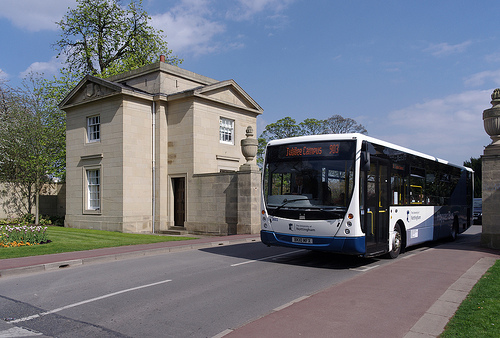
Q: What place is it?
A: It is a road.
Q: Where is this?
A: This is at the road.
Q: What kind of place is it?
A: It is a road.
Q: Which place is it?
A: It is a road.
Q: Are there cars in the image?
A: No, there are no cars.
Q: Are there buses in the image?
A: Yes, there is a bus.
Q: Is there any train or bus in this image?
A: Yes, there is a bus.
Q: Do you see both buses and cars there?
A: No, there is a bus but no cars.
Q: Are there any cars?
A: No, there are no cars.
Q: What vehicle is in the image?
A: The vehicle is a bus.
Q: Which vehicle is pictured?
A: The vehicle is a bus.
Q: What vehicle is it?
A: The vehicle is a bus.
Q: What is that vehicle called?
A: This is a bus.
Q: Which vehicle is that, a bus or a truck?
A: This is a bus.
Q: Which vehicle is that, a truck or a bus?
A: This is a bus.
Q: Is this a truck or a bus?
A: This is a bus.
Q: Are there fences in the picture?
A: No, there are no fences.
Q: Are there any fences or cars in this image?
A: No, there are no fences or cars.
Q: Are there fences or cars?
A: No, there are no cars or fences.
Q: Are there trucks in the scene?
A: No, there are no trucks.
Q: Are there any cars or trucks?
A: No, there are no trucks or cars.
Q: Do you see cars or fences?
A: No, there are no cars or fences.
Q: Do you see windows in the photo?
A: Yes, there is a window.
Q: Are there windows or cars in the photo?
A: Yes, there is a window.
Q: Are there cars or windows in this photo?
A: Yes, there is a window.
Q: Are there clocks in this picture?
A: No, there are no clocks.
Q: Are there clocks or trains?
A: No, there are no clocks or trains.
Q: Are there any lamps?
A: No, there are no lamps.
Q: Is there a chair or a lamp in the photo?
A: No, there are no lamps or chairs.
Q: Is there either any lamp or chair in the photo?
A: No, there are no lamps or chairs.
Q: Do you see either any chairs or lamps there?
A: No, there are no lamps or chairs.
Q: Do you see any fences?
A: No, there are no fences.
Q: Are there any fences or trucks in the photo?
A: No, there are no fences or trucks.